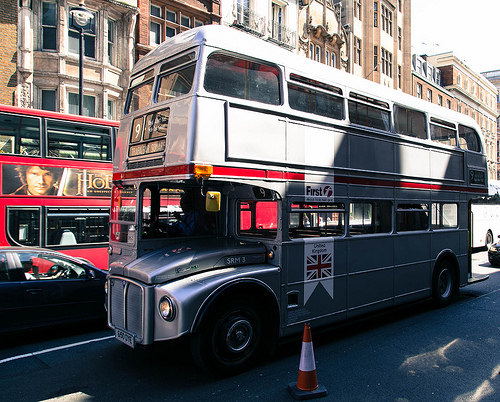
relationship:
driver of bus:
[152, 188, 234, 252] [103, 22, 492, 380]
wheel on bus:
[191, 282, 282, 372] [103, 22, 492, 380]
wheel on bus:
[426, 243, 470, 308] [103, 22, 492, 380]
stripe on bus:
[111, 157, 498, 194] [103, 22, 492, 380]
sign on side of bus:
[298, 167, 338, 204] [128, 59, 388, 334]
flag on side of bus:
[302, 236, 337, 302] [103, 22, 492, 380]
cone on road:
[287, 320, 328, 400] [0, 253, 499, 398]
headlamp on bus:
[156, 295, 176, 322] [103, 22, 492, 380]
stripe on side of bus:
[107, 162, 484, 189] [103, 22, 492, 380]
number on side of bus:
[224, 251, 250, 269] [101, 7, 352, 243]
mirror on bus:
[187, 170, 248, 233] [71, 87, 476, 373]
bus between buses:
[1, 104, 125, 335] [10, 111, 262, 243]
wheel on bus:
[425, 239, 465, 310] [103, 22, 492, 380]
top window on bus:
[203, 47, 283, 107] [103, 22, 492, 380]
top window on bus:
[287, 72, 345, 122] [103, 22, 492, 380]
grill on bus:
[106, 273, 145, 338] [103, 22, 492, 380]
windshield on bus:
[106, 182, 139, 242] [81, 2, 348, 311]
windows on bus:
[291, 201, 465, 242] [114, 36, 499, 346]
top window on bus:
[348, 84, 393, 133] [103, 22, 492, 380]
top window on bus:
[392, 97, 428, 142] [103, 22, 492, 380]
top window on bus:
[428, 111, 458, 150] [103, 22, 492, 380]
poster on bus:
[303, 167, 336, 204] [103, 22, 492, 380]